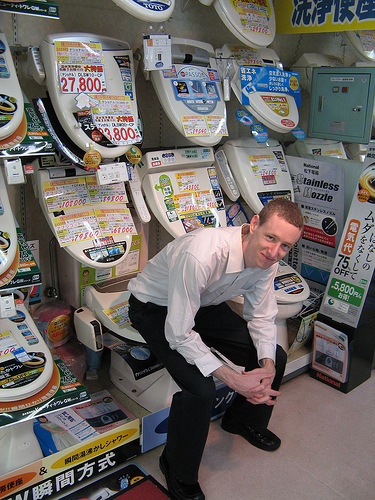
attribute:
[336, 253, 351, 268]
number — black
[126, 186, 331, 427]
man — young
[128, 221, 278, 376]
shirt — white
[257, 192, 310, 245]
hair — short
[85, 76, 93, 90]
number — red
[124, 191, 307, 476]
man — young, light skinned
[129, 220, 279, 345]
shirt — white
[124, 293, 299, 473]
pants — black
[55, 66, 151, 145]
numbers — red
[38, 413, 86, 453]
lady — light skinned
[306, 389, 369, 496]
floor — light brown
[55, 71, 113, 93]
number — red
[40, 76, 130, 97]
number — red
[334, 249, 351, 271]
number — black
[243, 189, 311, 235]
hair — light brown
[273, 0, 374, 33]
sign — yellow and blue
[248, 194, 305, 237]
hair — dark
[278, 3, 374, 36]
sign — yellow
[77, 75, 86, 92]
number — red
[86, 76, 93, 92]
number — red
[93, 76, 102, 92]
number — red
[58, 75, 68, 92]
number — red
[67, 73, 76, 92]
number — red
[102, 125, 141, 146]
number — red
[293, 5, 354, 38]
lettering — blue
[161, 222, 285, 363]
shirt — white